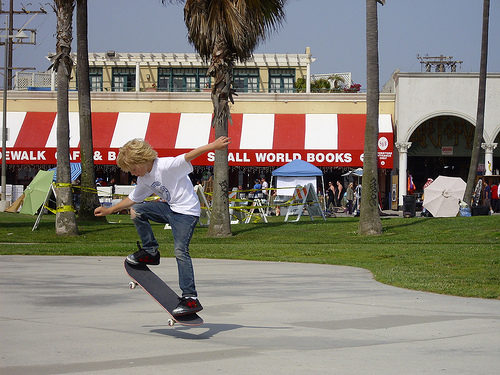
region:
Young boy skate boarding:
[96, 130, 239, 364]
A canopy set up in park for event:
[268, 160, 338, 219]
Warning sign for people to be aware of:
[276, 179, 338, 231]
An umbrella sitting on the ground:
[428, 170, 470, 230]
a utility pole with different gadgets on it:
[0, 0, 59, 90]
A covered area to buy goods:
[3, 103, 390, 210]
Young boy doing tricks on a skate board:
[112, 142, 233, 339]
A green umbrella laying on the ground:
[22, 155, 55, 225]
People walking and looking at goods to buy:
[325, 168, 351, 224]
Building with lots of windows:
[90, 46, 309, 101]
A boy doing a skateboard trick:
[67, 130, 252, 340]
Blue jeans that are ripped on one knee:
[90, 195, 245, 315]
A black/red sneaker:
[155, 290, 210, 320]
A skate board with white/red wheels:
[110, 245, 205, 330]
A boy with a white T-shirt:
[90, 125, 240, 315]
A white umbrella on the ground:
[415, 160, 471, 230]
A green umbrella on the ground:
[15, 165, 57, 220]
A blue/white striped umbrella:
[35, 146, 87, 181]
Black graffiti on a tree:
[212, 172, 229, 202]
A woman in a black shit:
[322, 173, 337, 208]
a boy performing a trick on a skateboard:
[92, 135, 234, 331]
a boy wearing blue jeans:
[128, 195, 198, 296]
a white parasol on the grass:
[422, 174, 467, 216]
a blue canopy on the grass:
[269, 157, 325, 217]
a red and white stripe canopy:
[2, 112, 392, 167]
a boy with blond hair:
[114, 136, 157, 178]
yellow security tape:
[42, 181, 318, 214]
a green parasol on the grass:
[19, 168, 53, 215]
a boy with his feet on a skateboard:
[120, 240, 204, 326]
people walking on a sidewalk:
[249, 174, 355, 211]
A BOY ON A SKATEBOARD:
[87, 130, 235, 332]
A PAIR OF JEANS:
[125, 195, 205, 300]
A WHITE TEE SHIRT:
[125, 150, 210, 220]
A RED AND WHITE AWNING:
[1, 105, 398, 165]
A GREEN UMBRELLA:
[15, 161, 55, 216]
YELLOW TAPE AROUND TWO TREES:
[35, 175, 105, 225]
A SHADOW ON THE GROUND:
[145, 317, 241, 342]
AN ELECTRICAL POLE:
[0, 1, 52, 91]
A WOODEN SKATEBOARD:
[120, 254, 207, 327]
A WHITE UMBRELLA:
[419, 172, 471, 222]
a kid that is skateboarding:
[71, 91, 386, 372]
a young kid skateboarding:
[57, 101, 337, 373]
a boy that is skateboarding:
[55, 52, 242, 372]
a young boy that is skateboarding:
[50, 76, 336, 374]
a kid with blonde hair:
[87, 115, 174, 212]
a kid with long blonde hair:
[94, 111, 199, 205]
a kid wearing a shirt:
[87, 101, 250, 219]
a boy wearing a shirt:
[97, 115, 274, 284]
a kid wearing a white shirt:
[103, 133, 258, 262]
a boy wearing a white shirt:
[94, 98, 261, 279]